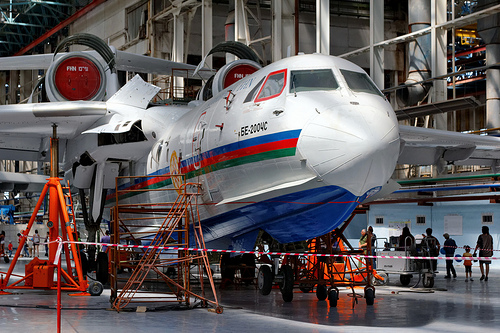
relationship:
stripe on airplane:
[110, 120, 315, 230] [17, 30, 498, 277]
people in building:
[359, 227, 483, 298] [5, 2, 495, 329]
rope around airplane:
[48, 233, 497, 274] [4, 30, 498, 300]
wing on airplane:
[404, 121, 494, 168] [22, 36, 434, 288]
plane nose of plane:
[342, 117, 402, 167] [0, 42, 498, 287]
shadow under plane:
[325, 307, 427, 324] [0, 42, 498, 287]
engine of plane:
[45, 50, 107, 101] [0, 42, 498, 287]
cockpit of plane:
[289, 68, 381, 95] [2, 50, 497, 304]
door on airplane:
[190, 106, 215, 207] [4, 30, 498, 300]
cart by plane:
[360, 231, 412, 285] [2, 50, 497, 304]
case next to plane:
[115, 189, 226, 319] [2, 50, 497, 304]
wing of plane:
[397, 124, 499, 165] [0, 42, 498, 287]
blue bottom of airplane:
[111, 182, 373, 299] [17, 30, 498, 277]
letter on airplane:
[249, 121, 268, 135] [0, 32, 499, 296]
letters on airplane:
[236, 124, 249, 139] [0, 32, 499, 296]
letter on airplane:
[261, 120, 268, 129] [0, 32, 499, 296]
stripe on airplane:
[103, 127, 304, 205] [4, 30, 498, 300]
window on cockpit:
[265, 73, 288, 99] [211, 66, 385, 140]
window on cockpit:
[293, 64, 339, 96] [211, 66, 385, 140]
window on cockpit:
[338, 63, 384, 97] [211, 66, 385, 140]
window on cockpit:
[243, 74, 262, 100] [211, 66, 385, 140]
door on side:
[194, 112, 214, 200] [144, 117, 307, 184]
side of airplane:
[144, 117, 307, 184] [140, 45, 482, 264]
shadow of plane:
[207, 266, 498, 330] [0, 42, 498, 287]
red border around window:
[248, 47, 293, 113] [239, 72, 299, 111]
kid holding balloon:
[457, 246, 472, 276] [448, 249, 460, 261]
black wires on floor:
[69, 301, 212, 316] [286, 296, 388, 320]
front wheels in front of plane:
[252, 262, 297, 298] [0, 42, 498, 287]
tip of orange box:
[26, 256, 55, 275] [319, 261, 353, 285]